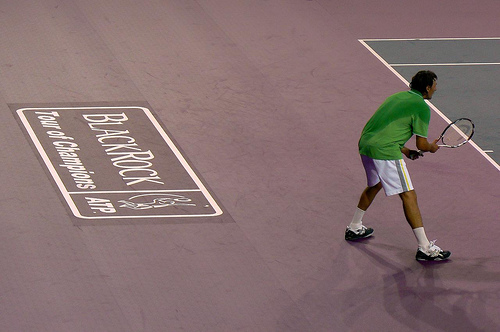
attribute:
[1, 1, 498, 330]
tennis court — green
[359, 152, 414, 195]
shorts — white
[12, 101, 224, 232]
logo — white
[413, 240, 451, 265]
tennis shoe — expensive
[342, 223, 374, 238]
tennis shoe — expensive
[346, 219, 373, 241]
shoes — white, black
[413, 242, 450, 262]
shoes — white, black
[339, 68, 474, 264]
tennis player — male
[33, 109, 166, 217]
letters — white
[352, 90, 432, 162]
shirt — soaked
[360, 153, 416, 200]
shorts — white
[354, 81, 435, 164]
shirt — green 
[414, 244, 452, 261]
shoe — black, white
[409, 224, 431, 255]
sock — white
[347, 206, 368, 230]
sock — white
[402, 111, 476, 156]
racquet — tennis racquet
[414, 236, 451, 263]
tennis shoe — black , white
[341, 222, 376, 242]
tennis shoe — black , white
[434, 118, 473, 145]
racket — white, black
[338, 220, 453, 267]
shoes — white, black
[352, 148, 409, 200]
shorts — white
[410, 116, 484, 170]
racket — for tennis, black, white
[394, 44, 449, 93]
hair — black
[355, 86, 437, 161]
shirt — green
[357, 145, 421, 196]
shorts — white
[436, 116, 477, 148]
racket — tennis racket, grey, white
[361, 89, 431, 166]
green shirt — polo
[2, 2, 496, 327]
court — for tennis, green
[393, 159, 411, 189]
stripe — green